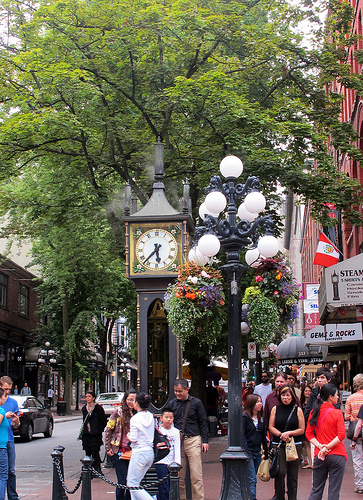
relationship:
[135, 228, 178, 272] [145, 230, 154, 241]
clock has numeral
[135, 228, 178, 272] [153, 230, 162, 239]
clock has numeral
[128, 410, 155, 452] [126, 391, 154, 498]
jacket on person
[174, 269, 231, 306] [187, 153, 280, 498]
flower by lamppost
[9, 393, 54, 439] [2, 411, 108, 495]
black car on road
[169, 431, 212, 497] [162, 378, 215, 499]
pants on man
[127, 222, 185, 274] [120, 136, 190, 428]
clock on tower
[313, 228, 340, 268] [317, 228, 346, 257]
flag on pole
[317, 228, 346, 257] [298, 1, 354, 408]
pole on building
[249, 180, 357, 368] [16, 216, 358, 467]
building in commercial area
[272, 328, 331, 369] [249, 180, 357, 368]
awning on building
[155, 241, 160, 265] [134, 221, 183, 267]
hand on clock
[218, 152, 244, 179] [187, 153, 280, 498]
globe on lamppost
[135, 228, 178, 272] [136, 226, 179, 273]
clock with numerals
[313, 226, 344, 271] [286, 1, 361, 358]
flag on building